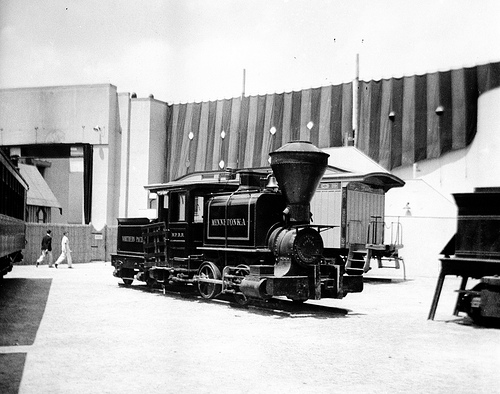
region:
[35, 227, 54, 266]
A man with black hair walking in a black coat.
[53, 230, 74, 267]
A person walking in all white.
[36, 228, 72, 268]
Two people walking close.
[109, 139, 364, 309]
The front of a black train with a large stack.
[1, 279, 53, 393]
Two dark shadows on the left.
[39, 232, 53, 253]
Black coat on a man walking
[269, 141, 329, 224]
Large black stack on a train.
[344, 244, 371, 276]
Metal steps going up to a lighter colored train car.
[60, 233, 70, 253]
White shirt on a person.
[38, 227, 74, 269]
Two people walking together.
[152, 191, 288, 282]
this is a train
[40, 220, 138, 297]
this is a man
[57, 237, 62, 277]
this is a white pair of pants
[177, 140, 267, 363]
the train is old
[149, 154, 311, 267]
the train is black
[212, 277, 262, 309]
this is a wheel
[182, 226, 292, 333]
the wheel is steel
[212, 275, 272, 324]
the wheel is black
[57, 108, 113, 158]
this is a building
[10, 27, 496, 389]
Black and white photo of train display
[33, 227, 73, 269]
Two people walking in background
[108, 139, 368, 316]
Old style train engine and freight car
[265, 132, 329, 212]
Metal train smoke stack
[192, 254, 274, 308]
Train's wheel and piston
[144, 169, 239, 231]
Engineer's cab on train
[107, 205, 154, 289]
Freight car on train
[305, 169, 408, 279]
Edge of rail car with steps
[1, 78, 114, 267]
People walking past grey building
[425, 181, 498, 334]
Edge of train freight car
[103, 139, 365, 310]
old train sitting on the ground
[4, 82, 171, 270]
large cement block building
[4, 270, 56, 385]
rectangular shadow on the ground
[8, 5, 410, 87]
sky with white clouds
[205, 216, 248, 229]
white lettering on the train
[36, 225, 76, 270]
two men walking together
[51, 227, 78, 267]
man wearing all white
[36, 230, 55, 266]
man with a dark top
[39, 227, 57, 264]
man wearing white pants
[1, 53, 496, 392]
items and people in an enclosure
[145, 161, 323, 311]
small locomotive in museum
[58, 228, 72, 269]
man walking in background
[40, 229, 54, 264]
man walking in background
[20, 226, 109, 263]
wooden fence by guys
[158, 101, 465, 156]
striped tent over wall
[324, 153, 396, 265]
train car behind locomotive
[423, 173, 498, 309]
back of coal car on right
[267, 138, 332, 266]
boiler of steam locomotive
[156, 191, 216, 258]
cabin of vintage locomotive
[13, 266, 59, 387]
shadow of train cars on ground